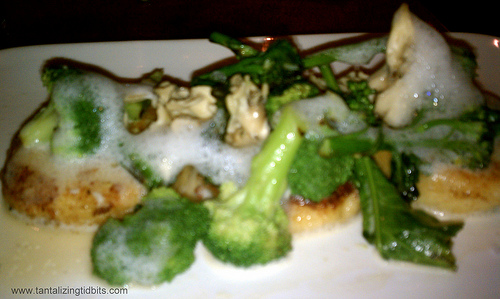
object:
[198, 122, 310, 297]
broccoli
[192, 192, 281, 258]
head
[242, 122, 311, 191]
stem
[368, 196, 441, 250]
leaf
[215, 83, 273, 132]
mushroom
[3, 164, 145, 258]
chicken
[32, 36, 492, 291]
plate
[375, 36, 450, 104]
dressing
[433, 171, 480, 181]
sauce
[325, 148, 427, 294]
spinach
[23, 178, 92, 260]
food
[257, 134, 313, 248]
piece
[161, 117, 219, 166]
foam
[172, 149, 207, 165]
vegetable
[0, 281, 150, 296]
address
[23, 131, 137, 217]
scallop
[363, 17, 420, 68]
chunk